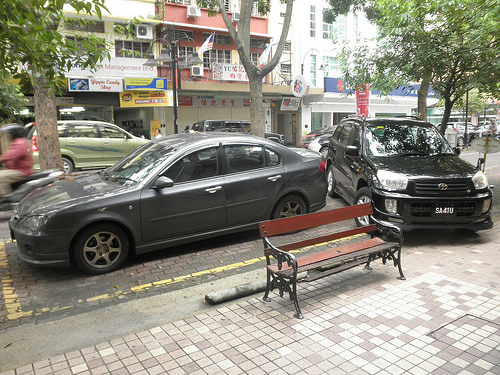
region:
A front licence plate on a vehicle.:
[433, 206, 455, 216]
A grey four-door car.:
[9, 132, 329, 280]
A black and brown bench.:
[253, 204, 410, 319]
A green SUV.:
[28, 119, 151, 172]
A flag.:
[197, 34, 218, 53]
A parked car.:
[17, 113, 332, 295]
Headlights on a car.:
[372, 166, 490, 191]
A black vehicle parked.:
[323, 116, 495, 233]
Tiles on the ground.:
[18, 204, 496, 371]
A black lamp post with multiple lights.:
[144, 32, 208, 135]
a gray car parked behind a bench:
[6, 131, 332, 274]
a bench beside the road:
[261, 200, 405, 321]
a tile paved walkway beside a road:
[0, 222, 499, 374]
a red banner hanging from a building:
[353, 76, 370, 118]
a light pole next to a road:
[148, 37, 201, 131]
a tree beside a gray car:
[213, 1, 297, 141]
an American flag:
[198, 30, 216, 61]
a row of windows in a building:
[114, 40, 154, 58]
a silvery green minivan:
[29, 121, 155, 173]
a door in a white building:
[273, 111, 291, 144]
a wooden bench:
[234, 196, 430, 306]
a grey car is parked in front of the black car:
[21, 126, 343, 265]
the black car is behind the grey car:
[318, 117, 482, 234]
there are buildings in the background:
[66, 3, 445, 118]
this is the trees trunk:
[18, 71, 87, 166]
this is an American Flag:
[186, 27, 233, 69]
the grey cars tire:
[78, 216, 137, 271]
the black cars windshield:
[365, 124, 449, 158]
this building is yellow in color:
[292, 8, 326, 91]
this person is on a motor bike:
[5, 117, 67, 197]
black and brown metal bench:
[255, 198, 407, 318]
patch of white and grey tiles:
[300, 270, 499, 374]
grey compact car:
[18, 128, 329, 271]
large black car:
[322, 114, 494, 229]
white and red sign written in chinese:
[216, 60, 253, 81]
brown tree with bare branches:
[212, 2, 293, 136]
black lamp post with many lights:
[142, 35, 202, 130]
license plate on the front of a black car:
[434, 206, 454, 213]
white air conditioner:
[187, 5, 202, 16]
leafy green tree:
[338, 4, 498, 121]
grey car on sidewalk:
[50, 137, 320, 267]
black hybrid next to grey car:
[325, 120, 484, 230]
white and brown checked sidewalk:
[117, 282, 491, 369]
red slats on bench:
[275, 224, 432, 278]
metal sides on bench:
[257, 242, 307, 323]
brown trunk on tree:
[30, 68, 64, 170]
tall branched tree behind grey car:
[209, 5, 294, 128]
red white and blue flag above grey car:
[195, 27, 231, 72]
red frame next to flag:
[162, 11, 266, 44]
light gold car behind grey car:
[27, 91, 174, 180]